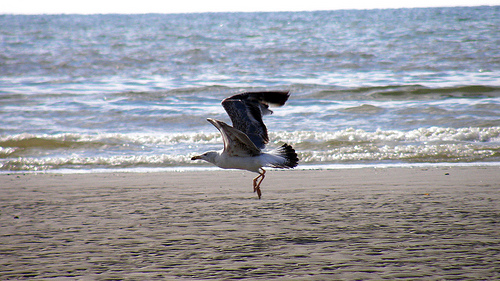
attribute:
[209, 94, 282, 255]
bird — large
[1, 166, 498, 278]
beach — sandy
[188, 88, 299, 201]
seagull — large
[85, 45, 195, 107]
water — LARGE, deep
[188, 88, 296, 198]
bird — LARGE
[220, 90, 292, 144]
wing — LARGE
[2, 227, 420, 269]
beach — long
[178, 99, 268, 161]
bird — flying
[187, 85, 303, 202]
bird — LARGE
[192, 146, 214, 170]
head — feathered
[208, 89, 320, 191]
bird — fly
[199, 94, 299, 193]
bird — LARGE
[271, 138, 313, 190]
tail — rear